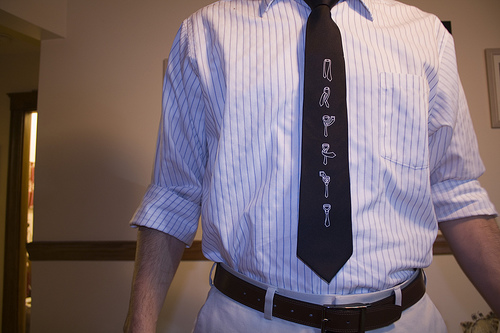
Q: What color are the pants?
A: Khaki.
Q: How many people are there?
A: One.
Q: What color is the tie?
A: Black.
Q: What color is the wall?
A: Tan.